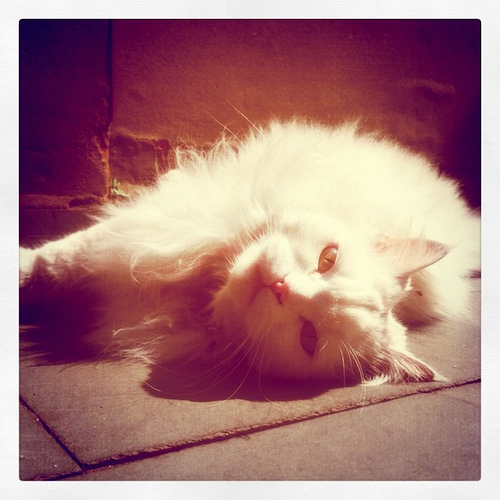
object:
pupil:
[321, 253, 336, 267]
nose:
[271, 274, 290, 306]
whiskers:
[224, 193, 281, 239]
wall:
[24, 24, 489, 264]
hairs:
[376, 221, 450, 266]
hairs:
[362, 356, 426, 390]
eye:
[317, 243, 340, 274]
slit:
[322, 254, 335, 266]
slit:
[301, 329, 318, 340]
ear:
[366, 348, 433, 385]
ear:
[362, 235, 447, 280]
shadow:
[12, 310, 353, 400]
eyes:
[300, 320, 319, 357]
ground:
[19, 353, 480, 481]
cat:
[20, 120, 482, 384]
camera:
[197, 223, 413, 363]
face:
[233, 222, 389, 378]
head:
[226, 211, 455, 385]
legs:
[18, 241, 168, 297]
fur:
[48, 105, 480, 248]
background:
[20, 18, 481, 264]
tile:
[19, 272, 479, 465]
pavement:
[24, 259, 478, 480]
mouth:
[249, 256, 268, 305]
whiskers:
[174, 324, 264, 409]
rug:
[22, 287, 480, 466]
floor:
[16, 211, 478, 476]